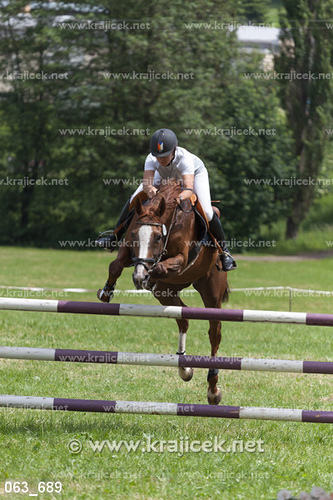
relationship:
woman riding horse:
[108, 100, 236, 290] [95, 170, 261, 445]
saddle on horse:
[117, 185, 223, 222] [95, 170, 261, 445]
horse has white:
[95, 170, 261, 445] [119, 199, 166, 281]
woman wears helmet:
[108, 100, 236, 290] [118, 115, 225, 186]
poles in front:
[16, 284, 315, 459] [66, 33, 267, 391]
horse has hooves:
[95, 170, 261, 445] [171, 371, 254, 418]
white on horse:
[119, 199, 166, 281] [95, 170, 261, 445]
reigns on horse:
[134, 171, 203, 311] [95, 170, 261, 445]